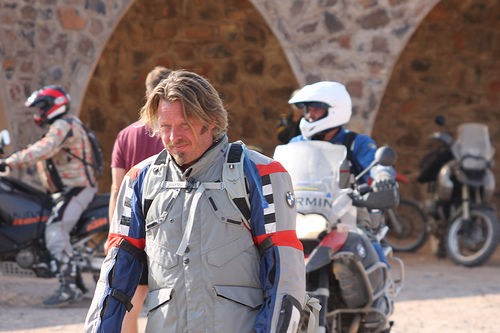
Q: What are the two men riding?
A: Motorcycles.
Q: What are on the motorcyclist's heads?
A: Helmets.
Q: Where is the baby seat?
A: On the bicycle.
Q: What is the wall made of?
A: Stone.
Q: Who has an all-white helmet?
A: The man on the motorcycle on the right.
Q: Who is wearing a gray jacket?
A: The blond-haired man in the center.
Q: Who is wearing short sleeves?
A: The man standing behind the blond-haired man.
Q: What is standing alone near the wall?
A: A bike.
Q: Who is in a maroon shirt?
A: The person.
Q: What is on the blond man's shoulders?
A: Backpack straps.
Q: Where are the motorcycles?
A: Near the wall.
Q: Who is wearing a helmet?
A: Motorcycle rider.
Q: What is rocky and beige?
A: The wall.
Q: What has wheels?
A: The motorcycles.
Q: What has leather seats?
A: The motorcycles.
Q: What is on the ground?
A: Dirt.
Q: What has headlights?
A: Motorcycles.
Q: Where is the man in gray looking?
A: Towards camera.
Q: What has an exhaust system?
A: Motorcycles.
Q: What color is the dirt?
A: Brown.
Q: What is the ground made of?
A: Dirt.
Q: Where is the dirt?
A: On the ground.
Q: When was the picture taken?
A: Daytime.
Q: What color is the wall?
A: Gray and brown.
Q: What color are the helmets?
A: White, black, and red.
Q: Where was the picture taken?
A: Front of building.